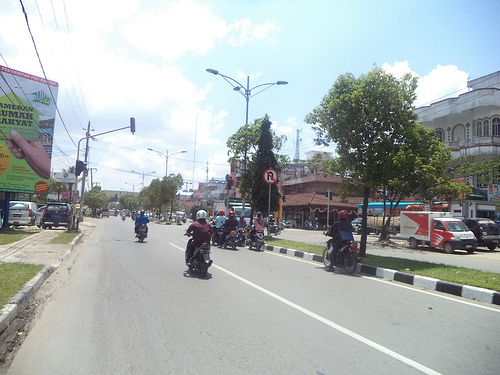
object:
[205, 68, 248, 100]
street lamps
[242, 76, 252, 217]
poles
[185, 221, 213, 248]
shirt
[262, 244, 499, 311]
border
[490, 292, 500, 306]
paint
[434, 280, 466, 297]
paint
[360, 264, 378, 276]
paint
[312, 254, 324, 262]
paint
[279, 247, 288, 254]
paint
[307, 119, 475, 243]
tree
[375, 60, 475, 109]
clouds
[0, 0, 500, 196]
sky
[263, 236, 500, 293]
ground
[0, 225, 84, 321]
ground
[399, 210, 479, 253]
red/white truck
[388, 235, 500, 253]
parking lot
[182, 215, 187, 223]
motorcycle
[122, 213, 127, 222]
motorcycle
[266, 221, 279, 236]
motorcycle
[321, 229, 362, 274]
motorcycle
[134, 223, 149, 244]
motorcycle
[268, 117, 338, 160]
clouds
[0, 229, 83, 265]
sidewalk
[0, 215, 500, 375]
road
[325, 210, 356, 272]
motorcyclist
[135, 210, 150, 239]
motorcyclist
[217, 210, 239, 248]
motorcyclist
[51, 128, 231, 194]
clouds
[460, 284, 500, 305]
white paint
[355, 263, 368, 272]
white paint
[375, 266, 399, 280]
white paint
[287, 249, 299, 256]
white paint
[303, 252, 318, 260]
white paint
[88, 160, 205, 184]
wires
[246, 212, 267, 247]
people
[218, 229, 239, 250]
motorcycle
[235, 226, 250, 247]
motorcycle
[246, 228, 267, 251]
motorcycle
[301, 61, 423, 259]
tree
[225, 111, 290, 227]
tree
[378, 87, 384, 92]
leaves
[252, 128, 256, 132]
leaves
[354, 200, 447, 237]
bus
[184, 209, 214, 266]
cyclist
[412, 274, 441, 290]
paint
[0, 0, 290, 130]
clouds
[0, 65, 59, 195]
billboard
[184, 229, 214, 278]
motorcycle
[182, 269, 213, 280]
shadow